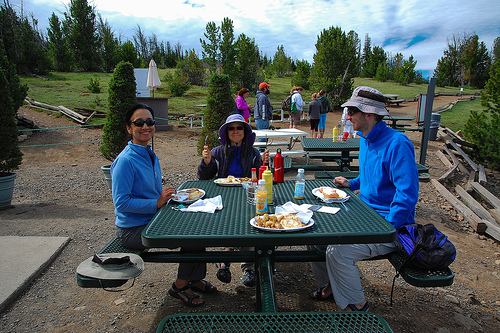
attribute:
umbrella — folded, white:
[114, 48, 185, 124]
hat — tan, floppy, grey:
[338, 73, 401, 125]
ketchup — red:
[254, 154, 275, 188]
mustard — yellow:
[254, 171, 286, 207]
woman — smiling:
[202, 107, 265, 161]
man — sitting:
[107, 122, 172, 242]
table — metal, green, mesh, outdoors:
[104, 150, 420, 331]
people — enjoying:
[97, 73, 421, 250]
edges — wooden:
[416, 87, 500, 259]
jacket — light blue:
[89, 135, 186, 233]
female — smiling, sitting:
[180, 101, 277, 198]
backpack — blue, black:
[379, 213, 473, 286]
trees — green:
[6, 6, 497, 158]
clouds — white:
[28, 0, 483, 94]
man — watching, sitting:
[318, 79, 410, 181]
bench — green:
[285, 128, 373, 187]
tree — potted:
[1, 47, 39, 208]